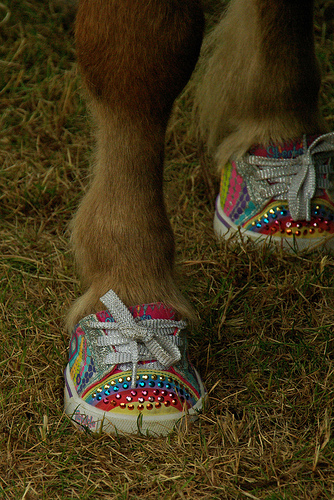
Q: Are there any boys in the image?
A: No, there are no boys.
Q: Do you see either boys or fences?
A: No, there are no boys or fences.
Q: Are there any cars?
A: No, there are no cars.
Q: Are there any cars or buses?
A: No, there are no cars or buses.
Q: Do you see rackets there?
A: No, there are no rackets.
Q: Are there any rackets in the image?
A: No, there are no rackets.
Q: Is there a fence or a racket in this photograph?
A: No, there are no rackets or fences.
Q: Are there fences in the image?
A: No, there are no fences.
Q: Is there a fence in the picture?
A: No, there are no fences.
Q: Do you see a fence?
A: No, there are no fences.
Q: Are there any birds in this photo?
A: No, there are no birds.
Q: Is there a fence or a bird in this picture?
A: No, there are no birds or fences.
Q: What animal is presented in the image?
A: The animal is a calf.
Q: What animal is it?
A: The animal is a calf.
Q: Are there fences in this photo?
A: No, there are no fences.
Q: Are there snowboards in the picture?
A: No, there are no snowboards.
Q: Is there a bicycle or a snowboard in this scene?
A: No, there are no snowboards or bicycles.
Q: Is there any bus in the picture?
A: No, there are no buses.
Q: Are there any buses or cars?
A: No, there are no buses or cars.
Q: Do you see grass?
A: Yes, there is grass.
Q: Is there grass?
A: Yes, there is grass.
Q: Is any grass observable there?
A: Yes, there is grass.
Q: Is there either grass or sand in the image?
A: Yes, there is grass.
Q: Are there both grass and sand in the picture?
A: No, there is grass but no sand.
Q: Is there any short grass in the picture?
A: Yes, there is short grass.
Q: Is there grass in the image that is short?
A: Yes, there is grass that is short.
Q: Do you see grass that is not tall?
A: Yes, there is short grass.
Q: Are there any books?
A: No, there are no books.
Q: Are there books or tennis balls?
A: No, there are no books or tennis balls.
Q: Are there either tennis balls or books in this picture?
A: No, there are no books or tennis balls.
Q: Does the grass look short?
A: Yes, the grass is short.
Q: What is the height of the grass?
A: The grass is short.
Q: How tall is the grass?
A: The grass is short.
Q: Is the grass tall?
A: No, the grass is short.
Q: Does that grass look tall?
A: No, the grass is short.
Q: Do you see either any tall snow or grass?
A: No, there is grass but it is short.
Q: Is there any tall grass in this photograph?
A: No, there is grass but it is short.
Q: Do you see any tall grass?
A: No, there is grass but it is short.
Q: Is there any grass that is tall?
A: No, there is grass but it is short.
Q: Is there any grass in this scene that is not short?
A: No, there is grass but it is short.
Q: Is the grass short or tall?
A: The grass is short.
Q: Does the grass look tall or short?
A: The grass is short.